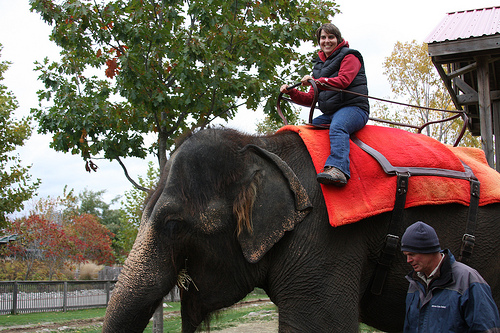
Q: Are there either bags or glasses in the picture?
A: No, there are no glasses or bags.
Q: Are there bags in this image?
A: No, there are no bags.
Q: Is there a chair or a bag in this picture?
A: No, there are no bags or chairs.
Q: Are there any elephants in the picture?
A: Yes, there is an elephant.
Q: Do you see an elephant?
A: Yes, there is an elephant.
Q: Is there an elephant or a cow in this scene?
A: Yes, there is an elephant.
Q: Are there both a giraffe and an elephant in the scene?
A: No, there is an elephant but no giraffes.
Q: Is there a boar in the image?
A: No, there are no boars.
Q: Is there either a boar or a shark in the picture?
A: No, there are no boars or sharks.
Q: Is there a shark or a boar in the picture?
A: No, there are no boars or sharks.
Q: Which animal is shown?
A: The animal is an elephant.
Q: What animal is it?
A: The animal is an elephant.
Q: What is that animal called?
A: This is an elephant.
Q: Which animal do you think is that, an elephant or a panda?
A: This is an elephant.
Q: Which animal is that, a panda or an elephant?
A: This is an elephant.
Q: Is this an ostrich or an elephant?
A: This is an elephant.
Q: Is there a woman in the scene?
A: Yes, there is a woman.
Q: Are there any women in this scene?
A: Yes, there is a woman.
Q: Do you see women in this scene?
A: Yes, there is a woman.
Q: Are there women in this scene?
A: Yes, there is a woman.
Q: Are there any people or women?
A: Yes, there is a woman.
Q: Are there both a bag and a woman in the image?
A: No, there is a woman but no bags.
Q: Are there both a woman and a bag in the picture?
A: No, there is a woman but no bags.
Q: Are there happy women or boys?
A: Yes, there is a happy woman.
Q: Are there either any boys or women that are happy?
A: Yes, the woman is happy.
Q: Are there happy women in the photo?
A: Yes, there is a happy woman.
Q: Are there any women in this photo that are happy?
A: Yes, there is a woman that is happy.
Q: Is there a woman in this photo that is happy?
A: Yes, there is a woman that is happy.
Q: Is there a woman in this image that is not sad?
A: Yes, there is a happy woman.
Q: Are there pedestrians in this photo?
A: No, there are no pedestrians.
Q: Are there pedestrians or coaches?
A: No, there are no pedestrians or coaches.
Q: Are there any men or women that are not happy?
A: No, there is a woman but she is happy.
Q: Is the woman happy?
A: Yes, the woman is happy.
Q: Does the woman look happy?
A: Yes, the woman is happy.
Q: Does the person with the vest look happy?
A: Yes, the woman is happy.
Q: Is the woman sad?
A: No, the woman is happy.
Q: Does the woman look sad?
A: No, the woman is happy.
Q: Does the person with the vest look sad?
A: No, the woman is happy.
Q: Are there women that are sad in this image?
A: No, there is a woman but she is happy.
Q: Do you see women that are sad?
A: No, there is a woman but she is happy.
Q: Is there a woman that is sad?
A: No, there is a woman but she is happy.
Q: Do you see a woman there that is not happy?
A: No, there is a woman but she is happy.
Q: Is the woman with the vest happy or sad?
A: The woman is happy.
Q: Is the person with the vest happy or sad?
A: The woman is happy.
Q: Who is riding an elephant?
A: The woman is riding an elephant.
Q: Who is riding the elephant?
A: The woman is riding an elephant.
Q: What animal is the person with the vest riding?
A: The woman is riding an elephant.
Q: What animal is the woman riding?
A: The woman is riding an elephant.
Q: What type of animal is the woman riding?
A: The woman is riding an elephant.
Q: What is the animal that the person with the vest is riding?
A: The animal is an elephant.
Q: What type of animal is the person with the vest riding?
A: The woman is riding an elephant.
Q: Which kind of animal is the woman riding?
A: The woman is riding an elephant.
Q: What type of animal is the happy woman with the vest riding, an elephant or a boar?
A: The woman is riding an elephant.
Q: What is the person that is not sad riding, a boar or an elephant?
A: The woman is riding an elephant.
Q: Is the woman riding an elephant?
A: Yes, the woman is riding an elephant.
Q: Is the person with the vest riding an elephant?
A: Yes, the woman is riding an elephant.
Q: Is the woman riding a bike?
A: No, the woman is riding an elephant.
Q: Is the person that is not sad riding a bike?
A: No, the woman is riding an elephant.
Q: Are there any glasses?
A: No, there are no glasses.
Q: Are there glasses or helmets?
A: No, there are no glasses or helmets.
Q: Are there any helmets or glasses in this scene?
A: No, there are no glasses or helmets.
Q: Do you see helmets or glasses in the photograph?
A: No, there are no glasses or helmets.